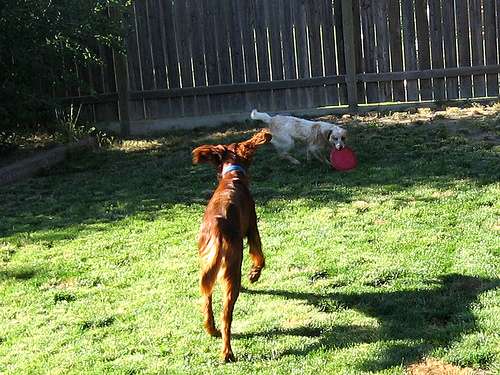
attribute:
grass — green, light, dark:
[288, 213, 444, 286]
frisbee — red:
[331, 148, 356, 169]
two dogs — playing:
[183, 95, 374, 367]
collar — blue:
[220, 160, 254, 177]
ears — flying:
[184, 126, 277, 169]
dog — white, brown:
[245, 101, 361, 167]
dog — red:
[189, 124, 273, 361]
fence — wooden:
[135, 5, 486, 102]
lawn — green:
[42, 200, 169, 357]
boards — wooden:
[169, 25, 266, 82]